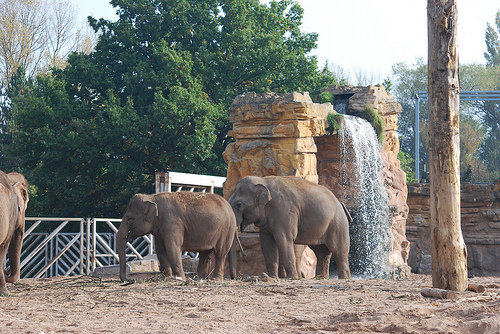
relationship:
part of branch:
[200, 33, 252, 63] [240, 54, 315, 92]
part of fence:
[37, 203, 98, 257] [0, 162, 234, 283]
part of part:
[418, 0, 485, 291] [430, 0, 470, 291]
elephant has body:
[109, 182, 239, 279] [154, 198, 236, 249]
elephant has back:
[109, 182, 239, 279] [133, 188, 224, 205]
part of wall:
[430, 0, 470, 291] [381, 185, 499, 268]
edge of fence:
[20, 184, 117, 289] [0, 162, 234, 283]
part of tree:
[200, 33, 252, 63] [4, 2, 312, 284]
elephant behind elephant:
[230, 172, 355, 280] [109, 182, 239, 279]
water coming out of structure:
[329, 108, 399, 271] [211, 84, 414, 273]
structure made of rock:
[211, 84, 414, 273] [230, 104, 299, 179]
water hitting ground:
[329, 108, 399, 271] [4, 251, 499, 331]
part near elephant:
[430, 0, 470, 291] [117, 193, 240, 279]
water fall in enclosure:
[329, 108, 399, 271] [2, 2, 495, 331]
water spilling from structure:
[329, 108, 399, 271] [203, 84, 414, 278]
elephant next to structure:
[230, 172, 355, 280] [203, 84, 414, 278]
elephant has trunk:
[109, 182, 239, 279] [108, 222, 137, 289]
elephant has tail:
[109, 182, 239, 279] [230, 212, 249, 252]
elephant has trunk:
[230, 172, 355, 280] [224, 207, 249, 282]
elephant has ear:
[109, 182, 239, 279] [138, 191, 163, 218]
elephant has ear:
[230, 172, 355, 280] [242, 170, 281, 202]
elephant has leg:
[109, 182, 239, 279] [167, 245, 191, 284]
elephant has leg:
[230, 172, 355, 280] [270, 216, 308, 286]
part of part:
[407, 82, 434, 192] [415, 82, 421, 183]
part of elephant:
[127, 162, 169, 245] [109, 182, 239, 279]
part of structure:
[234, 95, 392, 189] [203, 84, 414, 278]